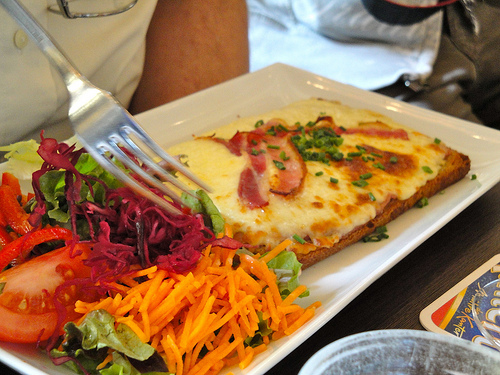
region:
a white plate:
[7, 56, 498, 351]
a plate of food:
[9, 71, 499, 372]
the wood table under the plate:
[426, 245, 473, 274]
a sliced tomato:
[5, 255, 105, 330]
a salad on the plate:
[9, 149, 258, 371]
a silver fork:
[19, 20, 209, 212]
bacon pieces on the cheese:
[238, 123, 300, 203]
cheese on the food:
[205, 193, 370, 228]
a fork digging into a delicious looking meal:
[0, 0, 217, 220]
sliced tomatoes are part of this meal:
[1, 240, 117, 341]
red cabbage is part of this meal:
[30, 131, 215, 263]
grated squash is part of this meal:
[73, 235, 310, 372]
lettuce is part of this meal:
[52, 304, 174, 374]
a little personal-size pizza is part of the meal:
[150, 90, 480, 275]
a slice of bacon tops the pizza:
[224, 119, 312, 205]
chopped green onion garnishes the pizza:
[253, 110, 380, 191]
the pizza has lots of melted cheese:
[172, 95, 449, 250]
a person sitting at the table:
[6, 1, 245, 118]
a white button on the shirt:
[14, 28, 27, 45]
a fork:
[17, 20, 207, 214]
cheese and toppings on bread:
[199, 96, 446, 249]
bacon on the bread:
[241, 127, 299, 194]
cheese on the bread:
[202, 76, 429, 235]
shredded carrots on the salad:
[128, 278, 278, 348]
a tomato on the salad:
[13, 253, 114, 341]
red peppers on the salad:
[11, 203, 48, 250]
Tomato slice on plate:
[1, 250, 108, 352]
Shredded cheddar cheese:
[152, 270, 242, 364]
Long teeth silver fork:
[60, 80, 215, 217]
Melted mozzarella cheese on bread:
[189, 143, 228, 179]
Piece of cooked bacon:
[231, 133, 273, 210]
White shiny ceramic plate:
[231, 62, 291, 106]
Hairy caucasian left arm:
[130, 1, 252, 115]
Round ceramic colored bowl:
[295, 325, 497, 373]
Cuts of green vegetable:
[294, 125, 345, 165]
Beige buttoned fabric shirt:
[1, 5, 157, 133]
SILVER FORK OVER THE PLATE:
[109, 136, 173, 190]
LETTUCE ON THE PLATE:
[96, 324, 126, 364]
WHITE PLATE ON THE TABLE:
[347, 254, 392, 289]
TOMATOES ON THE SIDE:
[20, 260, 84, 316]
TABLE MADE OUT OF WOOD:
[392, 268, 422, 314]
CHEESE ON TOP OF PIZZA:
[284, 201, 306, 228]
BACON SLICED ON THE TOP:
[242, 171, 263, 201]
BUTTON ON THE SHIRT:
[13, 31, 31, 51]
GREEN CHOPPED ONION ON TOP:
[360, 175, 374, 184]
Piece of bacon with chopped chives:
[226, 119, 308, 209]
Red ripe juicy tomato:
[2, 238, 107, 347]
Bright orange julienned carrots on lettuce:
[69, 236, 321, 371]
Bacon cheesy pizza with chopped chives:
[159, 92, 473, 267]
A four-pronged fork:
[2, 5, 214, 215]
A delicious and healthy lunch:
[6, 61, 498, 373]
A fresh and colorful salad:
[6, 137, 314, 372]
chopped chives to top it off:
[251, 107, 478, 242]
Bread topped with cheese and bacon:
[171, 95, 473, 265]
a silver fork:
[60, 60, 210, 218]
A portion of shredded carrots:
[119, 241, 309, 350]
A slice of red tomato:
[5, 224, 104, 344]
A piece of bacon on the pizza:
[225, 123, 307, 212]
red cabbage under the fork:
[60, 174, 192, 268]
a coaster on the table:
[419, 249, 499, 339]